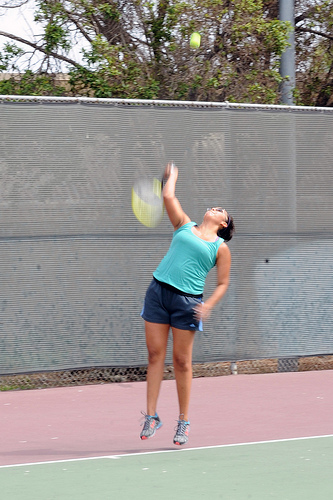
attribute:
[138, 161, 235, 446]
woman — jumping, playing tennis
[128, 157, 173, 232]
racket — yellow, black, swinging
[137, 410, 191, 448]
shoes — grey, pink, orange blue, gray, black, blue ad pik, pik ad blue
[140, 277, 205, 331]
shorts — blue, white, navy blue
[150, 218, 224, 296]
tank top — blue, light blue, gree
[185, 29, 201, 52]
tennis ball — yellow, airborne, flying, airbore, ellow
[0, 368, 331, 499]
court — green, red ad gree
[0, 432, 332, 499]
court portion — green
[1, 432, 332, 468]
stripe — white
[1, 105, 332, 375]
netting — gray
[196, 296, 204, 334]
trim — light blue, blue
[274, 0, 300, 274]
pole — gray, metal